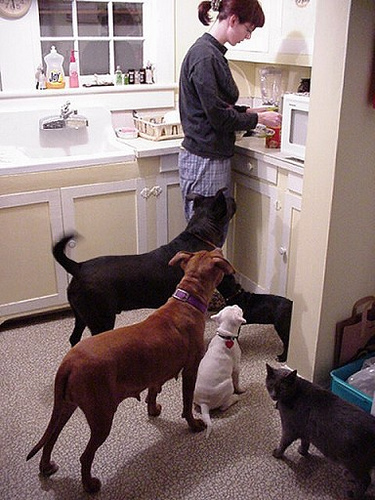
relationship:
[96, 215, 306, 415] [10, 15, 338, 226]
dogs in kitchen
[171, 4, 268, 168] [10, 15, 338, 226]
woman in kitchen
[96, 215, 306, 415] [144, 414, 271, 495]
dogs on floor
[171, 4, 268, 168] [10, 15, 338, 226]
woman on kitchen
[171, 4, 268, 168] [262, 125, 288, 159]
woman opening can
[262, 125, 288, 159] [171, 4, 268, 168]
can near woman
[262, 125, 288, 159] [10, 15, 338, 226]
can in kitchen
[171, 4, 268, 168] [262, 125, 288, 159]
woman has can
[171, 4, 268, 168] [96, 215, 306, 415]
woman above dogs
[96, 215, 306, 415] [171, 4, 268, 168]
dogs below woman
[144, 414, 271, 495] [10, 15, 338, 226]
floor in kitchen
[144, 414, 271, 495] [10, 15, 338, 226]
floor of kitchen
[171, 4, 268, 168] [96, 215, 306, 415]
woman near dogs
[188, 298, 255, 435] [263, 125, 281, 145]
pet waiting for food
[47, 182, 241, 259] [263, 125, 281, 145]
pet waiting for food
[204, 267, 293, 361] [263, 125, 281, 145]
dogs waiting for food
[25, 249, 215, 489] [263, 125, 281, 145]
pet waiting for food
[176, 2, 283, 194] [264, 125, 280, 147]
woman opeining can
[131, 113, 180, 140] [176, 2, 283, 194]
dish drainer behind woman